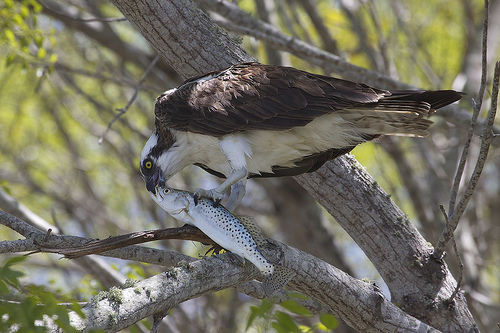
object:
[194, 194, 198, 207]
claw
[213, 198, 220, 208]
claw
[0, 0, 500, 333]
tree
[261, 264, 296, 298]
fish tail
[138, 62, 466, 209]
bird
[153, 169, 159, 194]
mouth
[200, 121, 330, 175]
underbelly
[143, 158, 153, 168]
eye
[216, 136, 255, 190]
leg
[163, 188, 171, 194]
eye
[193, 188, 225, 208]
bird talons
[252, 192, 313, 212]
wall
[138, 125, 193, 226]
birdandfish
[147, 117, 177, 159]
black stripe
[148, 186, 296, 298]
fish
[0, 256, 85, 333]
foliage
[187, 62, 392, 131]
feathers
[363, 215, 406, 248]
bark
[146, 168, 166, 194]
beak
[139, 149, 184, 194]
head